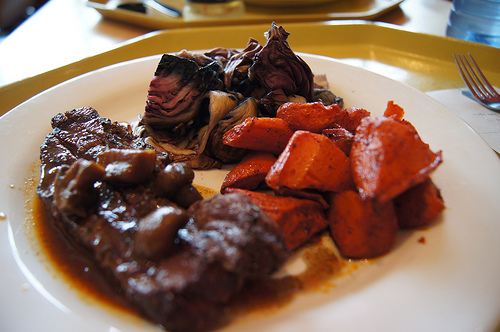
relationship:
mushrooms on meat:
[61, 130, 190, 257] [41, 105, 272, 314]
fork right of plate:
[442, 57, 499, 92] [359, 83, 466, 213]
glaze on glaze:
[108, 190, 251, 292] [38, 106, 284, 332]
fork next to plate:
[452, 52, 499, 114] [2, 50, 499, 328]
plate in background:
[65, 117, 443, 288] [124, 285, 482, 332]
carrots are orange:
[233, 101, 452, 275] [221, 55, 450, 281]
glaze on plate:
[38, 106, 284, 332] [2, 50, 499, 328]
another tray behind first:
[27, 124, 134, 254] [357, 286, 454, 332]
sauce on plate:
[174, 279, 323, 332] [2, 50, 499, 328]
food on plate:
[25, 19, 447, 329] [2, 50, 499, 328]